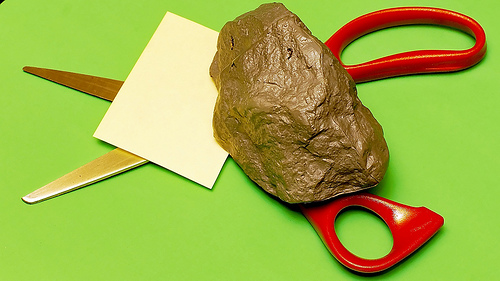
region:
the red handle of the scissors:
[313, 183, 445, 277]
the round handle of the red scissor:
[325, 0, 494, 86]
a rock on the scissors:
[212, 2, 390, 193]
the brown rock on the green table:
[210, 5, 387, 204]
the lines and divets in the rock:
[293, 100, 344, 165]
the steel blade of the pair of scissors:
[15, 53, 119, 104]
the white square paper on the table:
[92, 7, 215, 186]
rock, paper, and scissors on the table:
[20, 0, 487, 275]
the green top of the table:
[2, 213, 199, 278]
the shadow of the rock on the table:
[267, 199, 295, 231]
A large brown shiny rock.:
[208, 4, 390, 206]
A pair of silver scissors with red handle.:
[21, 6, 484, 275]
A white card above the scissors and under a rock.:
[93, 11, 233, 190]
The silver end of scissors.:
[22, 65, 149, 202]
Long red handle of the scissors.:
[316, 3, 488, 83]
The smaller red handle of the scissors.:
[292, 188, 442, 275]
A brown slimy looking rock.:
[208, 2, 391, 204]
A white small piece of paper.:
[93, 10, 230, 191]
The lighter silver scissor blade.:
[21, 145, 151, 202]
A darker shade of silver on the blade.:
[22, 64, 125, 99]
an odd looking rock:
[208, 5, 389, 205]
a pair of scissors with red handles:
[20, 5, 487, 273]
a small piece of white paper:
[92, 12, 236, 187]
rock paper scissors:
[22, 2, 484, 273]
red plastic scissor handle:
[324, 5, 486, 82]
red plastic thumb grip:
[304, 188, 441, 273]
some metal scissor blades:
[22, 65, 147, 205]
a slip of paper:
[93, 10, 229, 188]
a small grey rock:
[210, 0, 390, 202]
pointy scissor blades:
[22, 63, 149, 205]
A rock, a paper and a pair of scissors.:
[22, 1, 486, 276]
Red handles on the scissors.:
[300, 5, 483, 272]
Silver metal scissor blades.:
[18, 56, 148, 203]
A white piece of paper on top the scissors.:
[92, 10, 227, 190]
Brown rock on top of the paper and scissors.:
[208, 0, 388, 200]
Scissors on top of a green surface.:
[0, 0, 498, 278]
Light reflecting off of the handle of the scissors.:
[362, 195, 409, 225]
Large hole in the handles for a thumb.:
[320, 5, 485, 80]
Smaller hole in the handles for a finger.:
[301, 190, 442, 275]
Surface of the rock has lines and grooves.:
[210, 1, 390, 203]